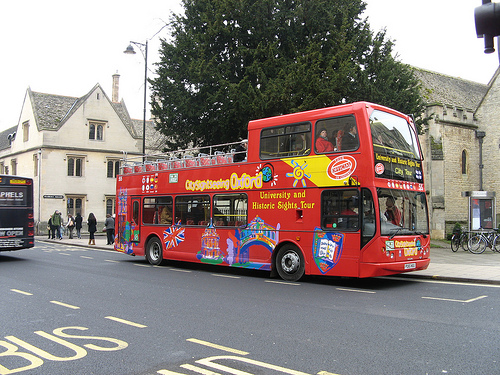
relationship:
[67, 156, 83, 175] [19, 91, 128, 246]
window on top of building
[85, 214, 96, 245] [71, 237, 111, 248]
pedestrin on top of sidewalk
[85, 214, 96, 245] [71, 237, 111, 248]
pedestrian on top of sidewalk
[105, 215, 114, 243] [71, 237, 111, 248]
pedestrian on top of sidewalk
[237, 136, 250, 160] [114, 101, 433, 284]
passenger on bus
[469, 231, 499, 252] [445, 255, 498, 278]
bike on top of sidewalk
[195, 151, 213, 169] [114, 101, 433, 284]
seat on top of bus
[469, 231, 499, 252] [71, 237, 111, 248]
bicycle near sidewalk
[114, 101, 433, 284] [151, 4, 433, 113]
bus near tree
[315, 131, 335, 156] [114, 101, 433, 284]
passenger inside bus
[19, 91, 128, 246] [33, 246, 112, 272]
building on street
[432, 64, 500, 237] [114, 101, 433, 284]
building near bus